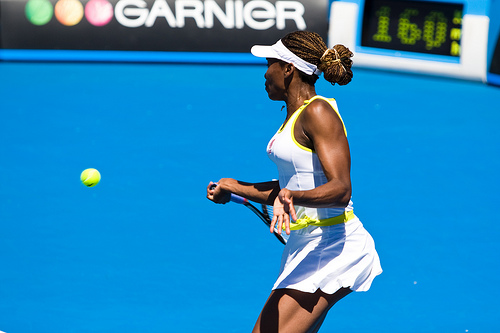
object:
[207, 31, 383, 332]
woman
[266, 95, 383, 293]
dress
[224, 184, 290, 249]
tennis racket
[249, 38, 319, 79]
hat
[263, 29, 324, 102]
head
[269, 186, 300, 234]
hand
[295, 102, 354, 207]
arm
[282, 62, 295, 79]
ear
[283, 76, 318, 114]
neck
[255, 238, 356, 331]
leg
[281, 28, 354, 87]
hair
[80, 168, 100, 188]
ball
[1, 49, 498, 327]
wall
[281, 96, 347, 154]
trim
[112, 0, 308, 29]
print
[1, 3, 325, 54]
background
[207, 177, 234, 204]
right hand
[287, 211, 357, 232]
belt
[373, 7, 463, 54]
text